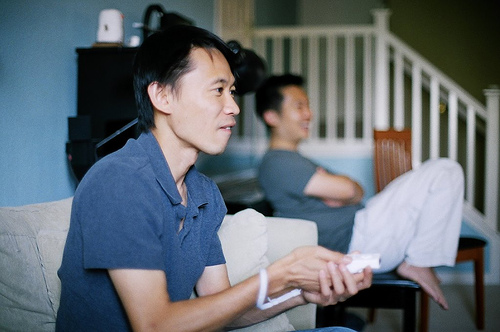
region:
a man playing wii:
[34, 3, 394, 328]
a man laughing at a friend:
[242, 61, 477, 301]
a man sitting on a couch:
[14, 32, 314, 321]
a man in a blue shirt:
[11, 29, 363, 326]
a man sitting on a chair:
[246, 54, 461, 329]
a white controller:
[238, 230, 430, 315]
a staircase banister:
[258, 24, 497, 241]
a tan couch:
[3, 197, 110, 329]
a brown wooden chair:
[361, 117, 495, 326]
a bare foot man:
[243, 71, 462, 305]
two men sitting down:
[53, 17, 466, 329]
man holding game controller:
[37, 18, 382, 330]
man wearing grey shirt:
[58, 21, 244, 328]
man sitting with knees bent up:
[255, 71, 469, 311]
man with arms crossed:
[253, 74, 373, 243]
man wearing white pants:
[256, 71, 466, 279]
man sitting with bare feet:
[254, 74, 464, 315]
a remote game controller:
[331, 250, 384, 276]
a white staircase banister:
[260, 28, 490, 228]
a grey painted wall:
[2, 5, 66, 197]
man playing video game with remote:
[53, 23, 381, 328]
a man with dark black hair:
[130, 22, 242, 151]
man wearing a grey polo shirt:
[62, 32, 377, 327]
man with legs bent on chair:
[254, 71, 462, 310]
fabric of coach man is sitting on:
[1, 198, 68, 329]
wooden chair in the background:
[372, 128, 494, 330]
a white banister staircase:
[217, 26, 495, 223]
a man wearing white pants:
[257, 75, 464, 304]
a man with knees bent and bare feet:
[253, 76, 460, 318]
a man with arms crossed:
[251, 73, 371, 217]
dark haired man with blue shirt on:
[64, 14, 278, 330]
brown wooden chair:
[366, 114, 489, 324]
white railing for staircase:
[256, 7, 499, 228]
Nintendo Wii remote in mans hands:
[261, 246, 399, 301]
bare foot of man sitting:
[396, 250, 456, 314]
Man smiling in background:
[253, 71, 366, 258]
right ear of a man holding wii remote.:
[141, 75, 172, 119]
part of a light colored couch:
[216, 206, 318, 330]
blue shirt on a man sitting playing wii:
[73, 160, 224, 330]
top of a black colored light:
[224, 36, 271, 98]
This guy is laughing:
[248, 71, 338, 153]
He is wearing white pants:
[352, 146, 474, 327]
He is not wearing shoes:
[382, 248, 467, 328]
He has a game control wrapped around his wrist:
[237, 234, 394, 325]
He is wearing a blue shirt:
[68, 118, 238, 329]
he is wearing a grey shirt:
[254, 136, 364, 253]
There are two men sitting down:
[60, 23, 481, 330]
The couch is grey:
[8, 193, 102, 327]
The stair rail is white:
[260, 13, 498, 161]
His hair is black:
[124, 17, 251, 124]